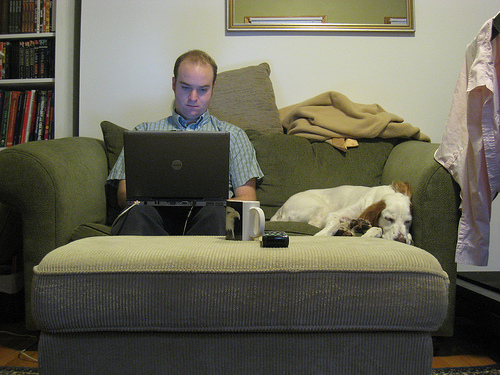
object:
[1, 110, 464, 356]
couch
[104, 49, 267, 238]
man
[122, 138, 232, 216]
laptop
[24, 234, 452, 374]
footstool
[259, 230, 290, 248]
remote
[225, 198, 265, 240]
cup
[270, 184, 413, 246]
dog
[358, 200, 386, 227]
ears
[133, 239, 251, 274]
pant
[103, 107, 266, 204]
shirt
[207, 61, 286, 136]
pillow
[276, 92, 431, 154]
blanket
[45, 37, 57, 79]
books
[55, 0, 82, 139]
coat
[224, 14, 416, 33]
mirror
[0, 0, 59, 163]
shelves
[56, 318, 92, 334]
floor